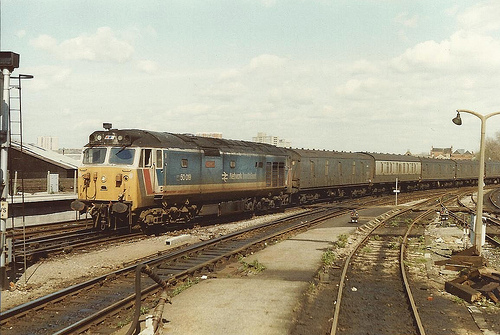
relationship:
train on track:
[99, 135, 265, 201] [18, 201, 73, 236]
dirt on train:
[316, 173, 345, 183] [99, 135, 265, 201]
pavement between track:
[228, 294, 306, 295] [18, 201, 73, 236]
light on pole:
[452, 111, 474, 128] [467, 139, 499, 190]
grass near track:
[245, 262, 264, 270] [18, 201, 73, 236]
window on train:
[104, 149, 130, 174] [99, 135, 265, 201]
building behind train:
[49, 136, 73, 153] [99, 135, 265, 201]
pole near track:
[467, 139, 499, 190] [18, 201, 73, 236]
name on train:
[216, 168, 239, 183] [99, 135, 265, 201]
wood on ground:
[136, 237, 182, 295] [189, 305, 211, 317]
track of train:
[18, 201, 73, 236] [99, 135, 265, 201]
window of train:
[104, 149, 130, 174] [99, 135, 265, 201]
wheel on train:
[136, 201, 164, 227] [99, 135, 265, 201]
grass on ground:
[245, 262, 264, 270] [189, 305, 211, 317]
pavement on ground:
[228, 294, 306, 295] [189, 305, 211, 317]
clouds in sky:
[345, 4, 421, 45] [163, 22, 184, 34]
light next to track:
[452, 111, 474, 128] [18, 201, 73, 236]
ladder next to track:
[0, 84, 30, 158] [18, 201, 73, 236]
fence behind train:
[60, 183, 69, 188] [99, 135, 265, 201]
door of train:
[170, 152, 239, 201] [99, 135, 265, 201]